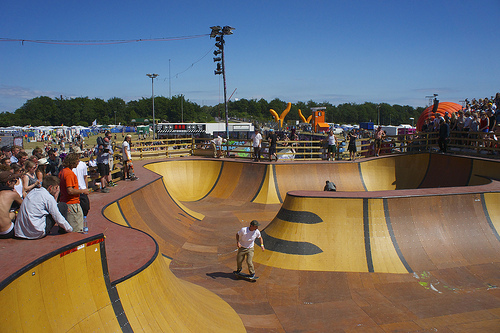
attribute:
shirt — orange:
[56, 167, 78, 204]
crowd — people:
[309, 125, 372, 162]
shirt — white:
[227, 220, 275, 252]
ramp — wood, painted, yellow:
[248, 186, 384, 279]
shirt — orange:
[52, 167, 84, 204]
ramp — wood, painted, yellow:
[4, 152, 499, 332]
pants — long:
[233, 247, 255, 275]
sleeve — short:
[234, 227, 246, 236]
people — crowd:
[4, 126, 140, 234]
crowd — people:
[372, 78, 498, 182]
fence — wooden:
[118, 130, 498, 161]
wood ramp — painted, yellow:
[127, 152, 468, 318]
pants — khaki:
[235, 245, 255, 275]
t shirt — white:
[237, 226, 260, 253]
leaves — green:
[113, 104, 136, 114]